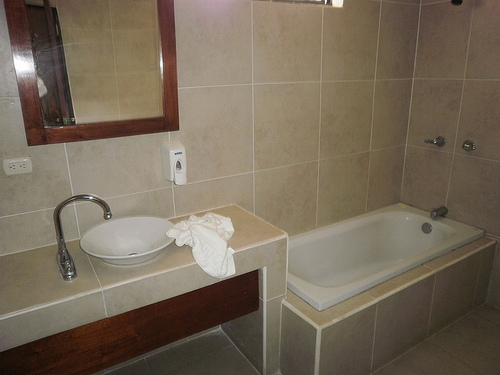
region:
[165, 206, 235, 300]
Towel on the counter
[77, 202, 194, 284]
Round sink under the faucet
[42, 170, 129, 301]
Curved and silver faucet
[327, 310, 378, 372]
Tub surrounded by tiles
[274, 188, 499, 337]
The bath tub is porcelain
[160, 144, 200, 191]
Soap dispenser on wall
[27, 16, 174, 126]
Reflection in the mirror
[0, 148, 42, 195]
Outlet on the wall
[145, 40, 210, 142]
Mirror is surrounded by wood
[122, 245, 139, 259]
Drain in the sink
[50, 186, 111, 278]
silver faucet by sink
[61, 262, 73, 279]
silver lever on faucet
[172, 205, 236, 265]
white towel on counter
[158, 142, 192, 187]
soap dispenser on wall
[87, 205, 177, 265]
white bowl of sink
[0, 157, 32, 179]
white electrical outlet on wall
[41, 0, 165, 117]
mirror on side of wall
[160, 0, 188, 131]
brown boarder of mirror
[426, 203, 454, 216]
silver faucet on wall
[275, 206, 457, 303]
white bathtub by wall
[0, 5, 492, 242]
square tiles on wall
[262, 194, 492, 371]
bathtub in corner of room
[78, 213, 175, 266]
round sink on counter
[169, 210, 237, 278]
white towel in a pile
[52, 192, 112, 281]
curved faucet over sink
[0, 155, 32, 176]
electrical outlet in wall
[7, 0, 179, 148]
wood frame on mirror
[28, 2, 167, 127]
reflection on wall mirror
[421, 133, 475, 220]
faucet and two handles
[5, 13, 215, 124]
A clean bathroom mirror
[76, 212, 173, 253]
A clean bathroom sink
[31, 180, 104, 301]
A clean bathroom tap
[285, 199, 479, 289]
A clean bath tub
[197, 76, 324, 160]
A clean bathroom wall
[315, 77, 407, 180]
A clean bathroom wall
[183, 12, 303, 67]
A clean bathroom wall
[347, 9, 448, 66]
A clean bathroom wall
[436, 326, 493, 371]
A clean bathroom floor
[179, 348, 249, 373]
A clean bathroom floor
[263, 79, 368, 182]
the wall is light brown in color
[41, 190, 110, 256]
the sink is silvery in color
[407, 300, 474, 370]
the floor has brown tiles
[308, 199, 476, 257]
the bathtab is white in color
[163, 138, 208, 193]
the swtch is white in color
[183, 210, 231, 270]
the towel is white in color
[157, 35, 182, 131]
the mirror frame is wooden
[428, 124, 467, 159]
the tap is silvery in color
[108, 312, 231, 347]
the sink frame is brown in color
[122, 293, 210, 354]
the sinkframe is wooden